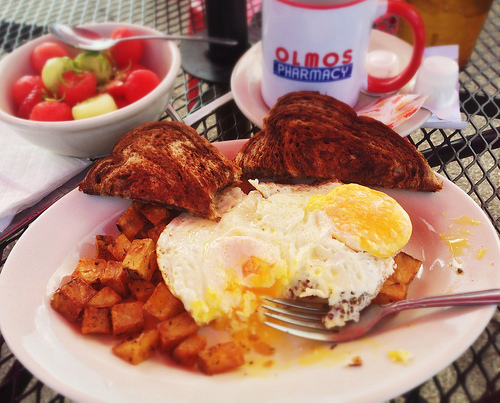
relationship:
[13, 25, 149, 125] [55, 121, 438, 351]
salad for breakfast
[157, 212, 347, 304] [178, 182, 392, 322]
sunny side up eggs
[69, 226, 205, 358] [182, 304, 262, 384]
seasoned breakfast potatoes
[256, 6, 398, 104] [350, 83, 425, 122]
beverage by sweetener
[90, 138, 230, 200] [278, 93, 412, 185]
crispy special toast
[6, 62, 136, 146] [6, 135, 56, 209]
bowl on napkin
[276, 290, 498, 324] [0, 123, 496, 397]
fork by plate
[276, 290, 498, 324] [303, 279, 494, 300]
fork on right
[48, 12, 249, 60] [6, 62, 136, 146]
spoon in bowl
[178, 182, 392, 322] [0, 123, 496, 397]
eggs on plate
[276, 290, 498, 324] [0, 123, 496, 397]
fork on plate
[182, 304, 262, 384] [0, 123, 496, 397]
potatoes on plate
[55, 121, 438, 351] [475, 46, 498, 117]
breakfast on table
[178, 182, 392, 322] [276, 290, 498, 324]
eggs and fork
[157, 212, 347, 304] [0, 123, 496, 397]
sunny side eggs on plate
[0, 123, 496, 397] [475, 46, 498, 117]
plate on table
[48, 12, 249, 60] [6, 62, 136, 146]
spoon on bowl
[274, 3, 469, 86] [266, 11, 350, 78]
cup for coffee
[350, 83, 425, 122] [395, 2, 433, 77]
sweetener pack red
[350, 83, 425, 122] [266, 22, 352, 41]
sweetener pack white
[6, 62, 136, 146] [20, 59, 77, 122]
bowl of tomatoes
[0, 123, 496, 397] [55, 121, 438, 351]
plate with breakfast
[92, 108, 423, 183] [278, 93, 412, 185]
slices of toast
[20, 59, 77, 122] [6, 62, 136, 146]
tomatoes in bowl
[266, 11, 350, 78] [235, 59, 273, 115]
coffee on saucer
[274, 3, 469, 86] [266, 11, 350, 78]
cup of coffee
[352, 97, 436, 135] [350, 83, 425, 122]
packs of sweetener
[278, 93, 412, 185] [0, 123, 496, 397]
toast on plate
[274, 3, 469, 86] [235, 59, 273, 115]
cup on saucer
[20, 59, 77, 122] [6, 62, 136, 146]
tomatoes on bowl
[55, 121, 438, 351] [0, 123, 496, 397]
food on plate